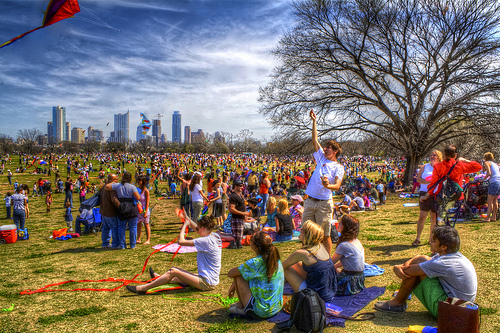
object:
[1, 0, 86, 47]
kite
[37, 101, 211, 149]
city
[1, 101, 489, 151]
background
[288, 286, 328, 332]
backpack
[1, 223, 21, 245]
cooler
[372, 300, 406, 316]
shoes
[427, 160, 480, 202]
shirt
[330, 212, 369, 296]
people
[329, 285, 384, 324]
blanket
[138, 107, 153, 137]
kite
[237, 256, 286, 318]
shirt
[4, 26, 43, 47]
tail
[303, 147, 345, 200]
shirt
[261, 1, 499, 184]
tree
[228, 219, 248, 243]
shorts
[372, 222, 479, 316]
person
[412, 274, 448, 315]
shorts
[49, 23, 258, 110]
sky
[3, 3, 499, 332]
scene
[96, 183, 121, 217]
around each other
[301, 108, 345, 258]
man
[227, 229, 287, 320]
woman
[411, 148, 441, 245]
woman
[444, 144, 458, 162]
red hair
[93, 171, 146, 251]
couple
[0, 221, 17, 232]
lid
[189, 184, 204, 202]
shirt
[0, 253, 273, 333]
ground